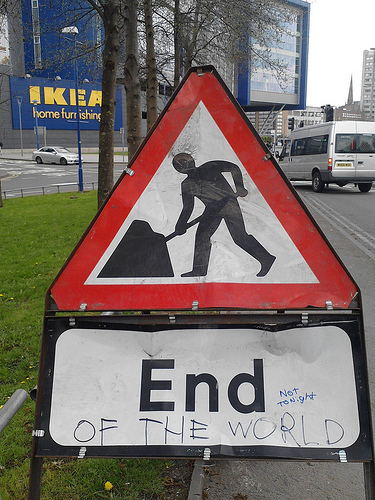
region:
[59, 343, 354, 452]
Graffiti on a sign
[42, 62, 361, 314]
A red, white and black sign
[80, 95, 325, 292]
A black and white symbol indicating men working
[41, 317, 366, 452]
The word end on a sign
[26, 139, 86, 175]
A silver car in the street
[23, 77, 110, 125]
A yellow and blue sign on a building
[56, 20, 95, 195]
A light on a blue pole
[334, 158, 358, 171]
A yellow license plate on a van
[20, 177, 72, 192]
A metal railing next to grass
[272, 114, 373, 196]
A silver van in the road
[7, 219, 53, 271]
the grass is green and short.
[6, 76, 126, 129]
a blue and yellow ikea furniture sign.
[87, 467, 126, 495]
a yellow flower.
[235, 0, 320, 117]
a big blue and grey building.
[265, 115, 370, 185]
a huge grey van.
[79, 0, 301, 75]
the trees are brown and thin.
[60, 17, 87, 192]
a tall thin blue light pole.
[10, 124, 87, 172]
a grey car is parked.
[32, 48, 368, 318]
a big red and black street sign.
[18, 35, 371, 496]
a huge sign says End of the World not tonight.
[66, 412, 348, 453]
words that someone wrote on a sign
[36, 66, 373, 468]
an end roadwork sign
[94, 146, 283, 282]
image of a man shoveling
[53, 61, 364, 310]
triangular shaped road sign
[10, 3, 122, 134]
big blue and yellow building sign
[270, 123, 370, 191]
large silver van driving on the street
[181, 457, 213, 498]
curb between grass and the road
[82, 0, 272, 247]
trees with no leaves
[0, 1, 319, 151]
large store for home furnishings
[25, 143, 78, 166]
silver car on the road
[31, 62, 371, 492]
a street sign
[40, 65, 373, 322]
street sign is triangle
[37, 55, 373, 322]
street sign is red and white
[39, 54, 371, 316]
center of sign is white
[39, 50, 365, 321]
border of sign is red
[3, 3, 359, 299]
an IKEA store on left side of road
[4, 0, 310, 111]
building is blue and gray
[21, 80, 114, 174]
a car in front an Ikea store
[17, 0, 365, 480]
trees behind a sign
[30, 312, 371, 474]
a white sign with handwriting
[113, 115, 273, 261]
red, white and black sign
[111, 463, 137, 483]
green grass on the ground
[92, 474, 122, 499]
yellow flower on the ground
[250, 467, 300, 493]
gray cement under sign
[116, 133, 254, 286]
black figure in photo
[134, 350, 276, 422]
the word "end" in the photo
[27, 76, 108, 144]
Ikea sign in the background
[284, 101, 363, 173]
car next to the grass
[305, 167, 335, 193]
tire on the car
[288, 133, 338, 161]
window on the van